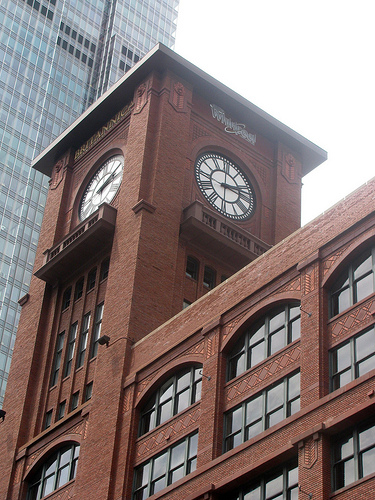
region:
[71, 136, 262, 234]
2 clocks on the building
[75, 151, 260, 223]
clocks are circular shaped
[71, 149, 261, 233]
clocks have black hands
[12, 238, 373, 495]
windows on building are arched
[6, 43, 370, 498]
the building is brown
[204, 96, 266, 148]
graffiti on the building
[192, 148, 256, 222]
numbers in roman numerals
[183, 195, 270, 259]
balcony under the clock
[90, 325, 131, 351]
camera on the building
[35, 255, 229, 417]
windows are rectangular shaped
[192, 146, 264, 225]
clock on the side of the tower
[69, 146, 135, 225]
black and white clock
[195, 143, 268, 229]
black and white clock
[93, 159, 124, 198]
two black clock hands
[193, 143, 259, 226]
black roman numeral around the clock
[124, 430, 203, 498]
window on the side of the building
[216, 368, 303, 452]
lines on the window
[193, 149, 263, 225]
clock indicating it's about 2:15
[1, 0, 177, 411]
building with numerous windows on it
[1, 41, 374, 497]
building is made of brick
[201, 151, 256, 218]
a clock on a castle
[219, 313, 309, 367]
a window on a building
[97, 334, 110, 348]
a light on the building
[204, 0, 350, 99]
misty skies above the building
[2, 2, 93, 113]
a storey building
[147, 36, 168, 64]
the peak of a building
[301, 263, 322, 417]
the column of a buiding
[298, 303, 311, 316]
a metal bar on the building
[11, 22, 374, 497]
it is big building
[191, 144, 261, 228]
it is wall clock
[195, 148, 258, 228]
it is white with black color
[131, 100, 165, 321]
it is brown color building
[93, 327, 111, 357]
it is light in the building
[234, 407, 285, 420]
it is a mirror in the building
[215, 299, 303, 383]
it is a window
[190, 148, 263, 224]
it is a roman letter clock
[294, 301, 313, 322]
it is an hanger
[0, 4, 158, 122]
it is glass building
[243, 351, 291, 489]
Brown building with black windows.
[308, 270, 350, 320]
Brown building with black windows.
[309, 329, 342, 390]
Brown building with black windows.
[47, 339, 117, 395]
Brown building with black windows.